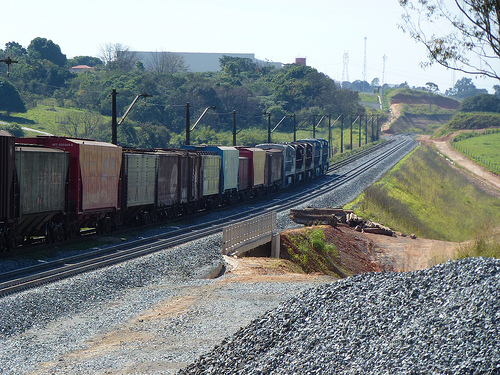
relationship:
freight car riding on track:
[18, 138, 117, 232] [2, 134, 394, 259]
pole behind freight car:
[111, 88, 118, 144] [18, 138, 117, 232]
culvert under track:
[239, 235, 306, 272] [2, 134, 394, 259]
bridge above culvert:
[222, 211, 277, 251] [239, 235, 306, 272]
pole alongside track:
[111, 88, 118, 144] [2, 134, 394, 259]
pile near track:
[180, 254, 499, 375] [2, 134, 394, 259]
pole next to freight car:
[111, 88, 118, 144] [18, 138, 117, 232]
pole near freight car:
[111, 88, 118, 144] [18, 138, 117, 232]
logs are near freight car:
[286, 209, 348, 224] [18, 138, 117, 232]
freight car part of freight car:
[18, 138, 117, 232] [0, 134, 335, 252]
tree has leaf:
[398, 1, 499, 80] [415, 34, 420, 39]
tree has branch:
[398, 1, 499, 80] [455, 1, 485, 33]